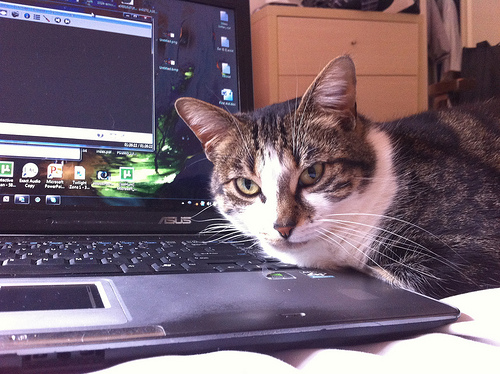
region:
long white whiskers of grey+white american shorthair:
[183, 201, 488, 300]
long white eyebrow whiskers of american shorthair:
[203, 54, 323, 164]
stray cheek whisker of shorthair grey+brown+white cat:
[348, 169, 418, 191]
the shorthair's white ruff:
[229, 125, 406, 275]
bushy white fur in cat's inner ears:
[173, 48, 357, 161]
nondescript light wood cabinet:
[248, 3, 433, 130]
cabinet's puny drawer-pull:
[347, 36, 359, 49]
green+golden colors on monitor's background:
[22, 93, 180, 208]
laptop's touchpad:
[0, 271, 153, 341]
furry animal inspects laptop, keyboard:
[1, 50, 498, 297]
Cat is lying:
[166, 31, 499, 299]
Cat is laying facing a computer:
[164, 50, 499, 310]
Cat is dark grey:
[160, 63, 498, 305]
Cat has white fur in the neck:
[316, 114, 405, 289]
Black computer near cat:
[8, 7, 461, 353]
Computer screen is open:
[0, 0, 257, 215]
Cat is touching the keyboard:
[0, 49, 499, 348]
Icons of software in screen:
[3, 159, 159, 184]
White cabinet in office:
[243, 5, 445, 112]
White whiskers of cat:
[168, 203, 468, 285]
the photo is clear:
[1, 0, 498, 365]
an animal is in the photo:
[176, 53, 496, 300]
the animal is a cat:
[160, 53, 498, 298]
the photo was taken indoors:
[3, 2, 483, 365]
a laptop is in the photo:
[3, 4, 293, 347]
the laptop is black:
[125, 279, 427, 367]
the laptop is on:
[1, 4, 230, 229]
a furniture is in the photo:
[262, 10, 497, 86]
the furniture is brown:
[258, 5, 456, 90]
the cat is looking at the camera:
[151, 101, 447, 266]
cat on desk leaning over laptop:
[58, 70, 466, 348]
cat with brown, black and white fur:
[166, 50, 463, 280]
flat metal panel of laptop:
[27, 245, 467, 351]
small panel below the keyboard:
[1, 257, 153, 322]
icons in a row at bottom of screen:
[6, 150, 156, 195]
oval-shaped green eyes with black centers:
[216, 161, 366, 201]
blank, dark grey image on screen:
[10, 15, 170, 130]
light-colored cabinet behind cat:
[245, 0, 440, 140]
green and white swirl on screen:
[75, 155, 180, 200]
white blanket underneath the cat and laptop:
[95, 257, 492, 364]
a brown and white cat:
[166, 52, 497, 294]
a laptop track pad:
[0, 282, 108, 322]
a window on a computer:
[0, 18, 151, 150]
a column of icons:
[205, 5, 237, 111]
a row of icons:
[0, 157, 140, 196]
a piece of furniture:
[251, 12, 420, 120]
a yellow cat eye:
[231, 171, 261, 202]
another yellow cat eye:
[297, 158, 326, 195]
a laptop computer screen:
[0, 15, 236, 211]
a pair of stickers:
[263, 266, 338, 285]